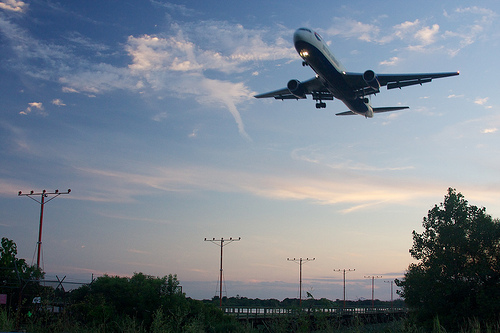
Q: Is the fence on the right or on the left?
A: The fence is on the left of the image.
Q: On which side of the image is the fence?
A: The fence is on the left of the image.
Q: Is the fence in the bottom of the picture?
A: Yes, the fence is in the bottom of the image.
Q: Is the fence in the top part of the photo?
A: No, the fence is in the bottom of the image.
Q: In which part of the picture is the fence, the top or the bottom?
A: The fence is in the bottom of the image.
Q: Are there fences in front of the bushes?
A: No, the fence is behind the bushes.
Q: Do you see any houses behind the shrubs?
A: No, there is a fence behind the shrubs.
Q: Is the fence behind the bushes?
A: Yes, the fence is behind the bushes.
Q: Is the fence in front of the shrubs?
A: No, the fence is behind the shrubs.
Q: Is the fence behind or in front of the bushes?
A: The fence is behind the bushes.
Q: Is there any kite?
A: No, there are no kites.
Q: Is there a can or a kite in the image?
A: No, there are no kites or cans.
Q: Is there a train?
A: Yes, there is a train.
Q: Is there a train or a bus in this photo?
A: Yes, there is a train.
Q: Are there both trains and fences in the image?
A: Yes, there are both a train and a fence.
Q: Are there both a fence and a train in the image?
A: Yes, there are both a train and a fence.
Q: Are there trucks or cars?
A: No, there are no cars or trucks.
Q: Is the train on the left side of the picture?
A: Yes, the train is on the left of the image.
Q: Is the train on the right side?
A: No, the train is on the left of the image.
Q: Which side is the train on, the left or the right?
A: The train is on the left of the image.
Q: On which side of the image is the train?
A: The train is on the left of the image.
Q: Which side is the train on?
A: The train is on the left of the image.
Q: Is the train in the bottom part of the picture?
A: Yes, the train is in the bottom of the image.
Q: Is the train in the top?
A: No, the train is in the bottom of the image.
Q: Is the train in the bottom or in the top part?
A: The train is in the bottom of the image.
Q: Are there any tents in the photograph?
A: No, there are no tents.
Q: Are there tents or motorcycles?
A: No, there are no tents or motorcycles.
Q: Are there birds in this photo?
A: No, there are no birds.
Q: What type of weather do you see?
A: It is cloudy.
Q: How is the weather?
A: It is cloudy.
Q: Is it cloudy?
A: Yes, it is cloudy.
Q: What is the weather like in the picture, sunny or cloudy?
A: It is cloudy.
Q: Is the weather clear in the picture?
A: No, it is cloudy.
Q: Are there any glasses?
A: No, there are no glasses.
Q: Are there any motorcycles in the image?
A: No, there are no motorcycles.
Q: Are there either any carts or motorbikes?
A: No, there are no motorbikes or carts.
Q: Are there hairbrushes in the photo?
A: No, there are no hairbrushes.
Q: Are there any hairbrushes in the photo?
A: No, there are no hairbrushes.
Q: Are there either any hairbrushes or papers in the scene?
A: No, there are no hairbrushes or papers.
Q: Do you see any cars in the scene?
A: No, there are no cars.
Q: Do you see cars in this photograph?
A: No, there are no cars.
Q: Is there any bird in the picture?
A: No, there are no birds.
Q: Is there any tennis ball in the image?
A: No, there are no tennis balls.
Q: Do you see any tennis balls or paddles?
A: No, there are no tennis balls or paddles.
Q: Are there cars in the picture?
A: No, there are no cars.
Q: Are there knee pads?
A: No, there are no knee pads.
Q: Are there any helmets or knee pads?
A: No, there are no knee pads or helmets.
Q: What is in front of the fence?
A: The bushes are in front of the fence.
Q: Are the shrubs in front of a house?
A: No, the shrubs are in front of a fence.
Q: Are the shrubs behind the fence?
A: No, the shrubs are in front of the fence.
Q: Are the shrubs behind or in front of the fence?
A: The shrubs are in front of the fence.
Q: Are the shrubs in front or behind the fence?
A: The shrubs are in front of the fence.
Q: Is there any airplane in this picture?
A: Yes, there is an airplane.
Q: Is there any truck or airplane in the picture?
A: Yes, there is an airplane.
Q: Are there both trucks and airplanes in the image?
A: No, there is an airplane but no trucks.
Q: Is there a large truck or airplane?
A: Yes, there is a large airplane.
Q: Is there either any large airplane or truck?
A: Yes, there is a large airplane.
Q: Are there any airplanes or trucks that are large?
A: Yes, the airplane is large.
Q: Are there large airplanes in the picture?
A: Yes, there is a large airplane.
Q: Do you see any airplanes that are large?
A: Yes, there is a large airplane.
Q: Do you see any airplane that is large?
A: Yes, there is an airplane that is large.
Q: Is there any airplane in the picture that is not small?
A: Yes, there is a large airplane.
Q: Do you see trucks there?
A: No, there are no trucks.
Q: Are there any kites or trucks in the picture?
A: No, there are no trucks or kites.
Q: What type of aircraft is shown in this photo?
A: The aircraft is an airplane.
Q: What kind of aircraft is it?
A: The aircraft is an airplane.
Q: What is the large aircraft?
A: The aircraft is an airplane.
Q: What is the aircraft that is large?
A: The aircraft is an airplane.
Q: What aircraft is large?
A: The aircraft is an airplane.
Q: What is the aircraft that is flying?
A: The aircraft is an airplane.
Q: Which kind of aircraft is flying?
A: The aircraft is an airplane.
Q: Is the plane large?
A: Yes, the plane is large.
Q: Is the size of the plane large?
A: Yes, the plane is large.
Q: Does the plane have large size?
A: Yes, the plane is large.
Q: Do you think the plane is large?
A: Yes, the plane is large.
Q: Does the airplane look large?
A: Yes, the airplane is large.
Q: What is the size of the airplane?
A: The airplane is large.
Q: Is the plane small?
A: No, the plane is large.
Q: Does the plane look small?
A: No, the plane is large.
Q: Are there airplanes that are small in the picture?
A: No, there is an airplane but it is large.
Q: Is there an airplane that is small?
A: No, there is an airplane but it is large.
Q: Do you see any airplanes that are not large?
A: No, there is an airplane but it is large.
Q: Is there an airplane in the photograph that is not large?
A: No, there is an airplane but it is large.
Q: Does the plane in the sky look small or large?
A: The plane is large.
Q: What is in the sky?
A: The plane is in the sky.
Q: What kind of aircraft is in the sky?
A: The aircraft is an airplane.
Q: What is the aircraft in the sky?
A: The aircraft is an airplane.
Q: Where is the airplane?
A: The airplane is in the sky.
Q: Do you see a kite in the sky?
A: No, there is an airplane in the sky.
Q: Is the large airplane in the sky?
A: Yes, the plane is in the sky.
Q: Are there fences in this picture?
A: Yes, there is a fence.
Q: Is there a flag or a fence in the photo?
A: Yes, there is a fence.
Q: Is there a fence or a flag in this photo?
A: Yes, there is a fence.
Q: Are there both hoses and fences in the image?
A: No, there is a fence but no hoses.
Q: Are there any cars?
A: No, there are no cars.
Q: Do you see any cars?
A: No, there are no cars.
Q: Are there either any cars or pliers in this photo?
A: No, there are no cars or pliers.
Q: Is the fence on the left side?
A: Yes, the fence is on the left of the image.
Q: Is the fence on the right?
A: No, the fence is on the left of the image.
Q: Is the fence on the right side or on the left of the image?
A: The fence is on the left of the image.